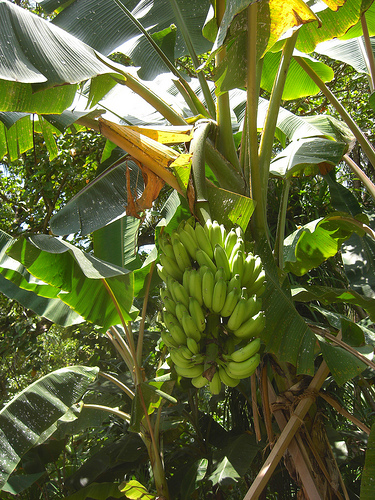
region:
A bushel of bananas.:
[156, 213, 256, 386]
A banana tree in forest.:
[99, 64, 342, 491]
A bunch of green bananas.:
[159, 215, 265, 388]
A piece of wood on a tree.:
[234, 329, 358, 498]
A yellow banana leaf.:
[101, 119, 193, 196]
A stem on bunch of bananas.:
[202, 324, 221, 381]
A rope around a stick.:
[287, 384, 327, 424]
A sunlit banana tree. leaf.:
[270, 1, 323, 37]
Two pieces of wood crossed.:
[253, 361, 322, 498]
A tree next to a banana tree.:
[21, 219, 184, 493]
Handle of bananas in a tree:
[142, 207, 280, 402]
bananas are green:
[141, 210, 276, 414]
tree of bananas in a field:
[10, 8, 373, 482]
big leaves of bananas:
[6, 0, 369, 105]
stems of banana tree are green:
[122, 52, 294, 220]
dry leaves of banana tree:
[240, 370, 356, 498]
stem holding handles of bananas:
[172, 108, 230, 224]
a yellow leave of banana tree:
[272, 1, 343, 40]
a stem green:
[198, 309, 229, 382]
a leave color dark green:
[4, 352, 127, 477]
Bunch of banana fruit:
[149, 220, 260, 391]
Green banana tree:
[64, 349, 188, 494]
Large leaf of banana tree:
[24, 231, 136, 339]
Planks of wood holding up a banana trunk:
[234, 394, 333, 496]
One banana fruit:
[238, 312, 264, 341]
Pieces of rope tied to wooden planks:
[267, 391, 318, 419]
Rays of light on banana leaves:
[187, 452, 240, 494]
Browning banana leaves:
[70, 482, 157, 498]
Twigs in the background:
[1, 161, 59, 230]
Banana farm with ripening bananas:
[3, 323, 360, 498]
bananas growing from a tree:
[141, 200, 271, 405]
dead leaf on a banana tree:
[85, 110, 200, 227]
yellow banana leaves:
[217, 5, 337, 63]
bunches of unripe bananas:
[154, 219, 271, 415]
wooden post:
[267, 329, 333, 498]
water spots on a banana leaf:
[7, 362, 92, 475]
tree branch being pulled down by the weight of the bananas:
[160, 116, 240, 261]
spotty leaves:
[46, 161, 154, 237]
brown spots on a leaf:
[311, 154, 341, 185]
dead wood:
[236, 358, 290, 448]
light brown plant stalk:
[231, 366, 367, 498]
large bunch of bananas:
[155, 224, 277, 402]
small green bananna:
[229, 339, 268, 362]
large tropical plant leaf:
[5, 355, 110, 481]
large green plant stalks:
[205, 42, 289, 235]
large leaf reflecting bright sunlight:
[59, 45, 237, 147]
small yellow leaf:
[124, 471, 176, 494]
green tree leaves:
[6, 134, 143, 222]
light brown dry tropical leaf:
[86, 93, 199, 224]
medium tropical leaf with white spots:
[206, 3, 272, 98]